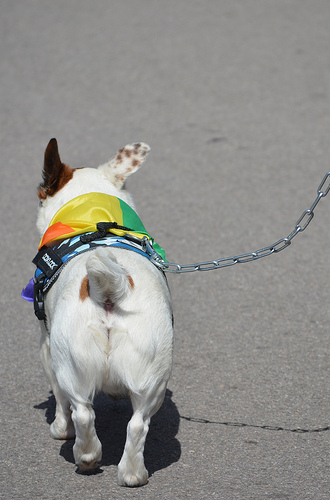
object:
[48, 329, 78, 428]
front leg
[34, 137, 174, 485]
dog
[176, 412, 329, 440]
shadow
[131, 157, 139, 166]
spots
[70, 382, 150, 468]
legs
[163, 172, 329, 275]
chain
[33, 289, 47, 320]
buckle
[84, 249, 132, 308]
tail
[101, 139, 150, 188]
dog's ear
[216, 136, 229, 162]
ground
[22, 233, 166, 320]
leash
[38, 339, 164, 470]
dog legs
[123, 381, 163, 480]
leg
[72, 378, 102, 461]
leg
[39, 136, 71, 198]
ear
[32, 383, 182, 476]
shadow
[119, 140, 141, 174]
spot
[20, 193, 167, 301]
fabric